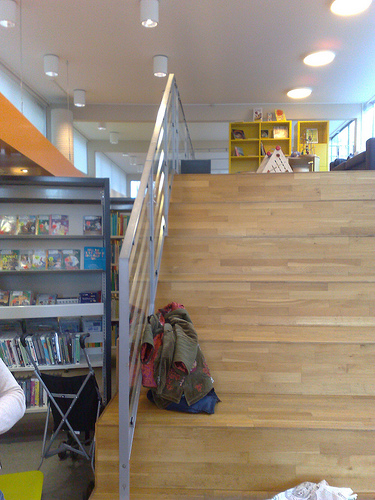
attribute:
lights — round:
[287, 0, 372, 101]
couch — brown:
[331, 141, 373, 168]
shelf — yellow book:
[222, 111, 334, 169]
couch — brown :
[319, 136, 363, 172]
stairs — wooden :
[93, 173, 363, 496]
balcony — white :
[112, 68, 197, 498]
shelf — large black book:
[2, 169, 119, 436]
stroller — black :
[16, 334, 93, 497]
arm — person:
[0, 359, 33, 437]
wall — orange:
[3, 94, 85, 182]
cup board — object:
[230, 100, 333, 170]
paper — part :
[270, 480, 359, 498]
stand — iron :
[110, 68, 194, 497]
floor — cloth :
[7, 465, 50, 497]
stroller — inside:
[14, 325, 102, 449]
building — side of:
[3, 4, 362, 483]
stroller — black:
[9, 328, 103, 458]